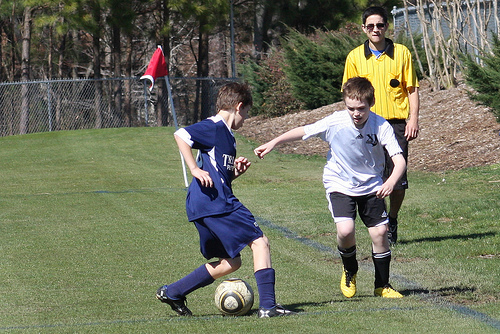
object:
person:
[154, 78, 305, 321]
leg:
[358, 194, 392, 286]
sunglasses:
[362, 20, 385, 31]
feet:
[339, 269, 360, 299]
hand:
[230, 155, 253, 177]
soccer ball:
[213, 273, 255, 315]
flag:
[138, 43, 169, 92]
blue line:
[250, 213, 339, 256]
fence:
[0, 75, 129, 138]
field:
[0, 124, 498, 330]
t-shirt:
[338, 39, 433, 122]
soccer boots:
[372, 283, 403, 299]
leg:
[325, 192, 359, 274]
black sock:
[368, 248, 392, 288]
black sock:
[333, 245, 360, 276]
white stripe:
[373, 251, 392, 260]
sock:
[366, 249, 395, 290]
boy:
[252, 74, 404, 300]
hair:
[339, 74, 375, 106]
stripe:
[337, 248, 357, 258]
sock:
[162, 260, 215, 300]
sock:
[252, 267, 277, 309]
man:
[338, 4, 421, 246]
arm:
[171, 121, 216, 173]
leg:
[231, 207, 275, 307]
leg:
[170, 221, 242, 294]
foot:
[372, 281, 402, 300]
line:
[250, 215, 498, 334]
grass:
[2, 125, 499, 334]